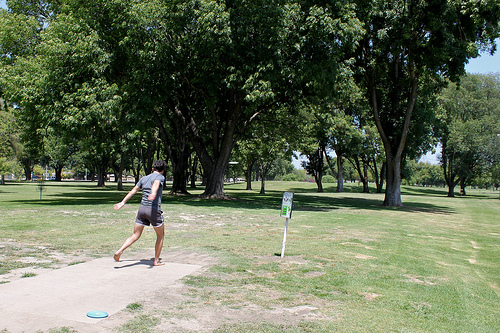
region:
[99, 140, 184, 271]
A man running in a field.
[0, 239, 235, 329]
a patch of dirt in a field.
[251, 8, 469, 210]
A tall green leafy tree.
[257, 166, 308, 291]
a sign near a patch of dirt.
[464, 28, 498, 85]
a section of a blue sky.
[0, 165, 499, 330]
a park with lots of green grass.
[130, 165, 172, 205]
a man wearing a gray t shirt.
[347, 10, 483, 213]
a tree with lots of green leaves.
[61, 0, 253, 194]
a tall leafy green tree.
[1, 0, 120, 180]
a tree with lots of leaves.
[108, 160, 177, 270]
This is a person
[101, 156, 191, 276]
This is a woman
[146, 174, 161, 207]
Hand of a person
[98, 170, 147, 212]
Hand of a person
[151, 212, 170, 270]
Leg of a person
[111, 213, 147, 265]
Leg of a person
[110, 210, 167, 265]
Legs of a person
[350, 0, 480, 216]
This is a tree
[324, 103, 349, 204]
This is a tree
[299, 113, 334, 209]
This is a tree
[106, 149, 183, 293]
man playing in park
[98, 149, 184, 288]
young man playing in park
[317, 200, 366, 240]
short green and brown grass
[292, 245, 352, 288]
short green and brown grass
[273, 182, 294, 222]
green and white sign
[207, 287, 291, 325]
short green and brown grass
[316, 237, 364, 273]
short green and brown grass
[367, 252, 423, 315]
short green and brown grass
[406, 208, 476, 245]
short green and brown grass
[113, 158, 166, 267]
man practicing yoga in a park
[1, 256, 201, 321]
yoga mat on grass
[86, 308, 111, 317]
green disc resting on a yoga mat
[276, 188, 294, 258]
green sign with white post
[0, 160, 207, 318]
man standing on a yoga mat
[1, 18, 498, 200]
trees in a park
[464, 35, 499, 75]
blue sky showing between trees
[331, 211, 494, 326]
grass in a park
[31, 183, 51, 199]
small shrub in a park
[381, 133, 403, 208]
trunk of a large tree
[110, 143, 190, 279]
this is a person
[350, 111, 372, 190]
this is a tree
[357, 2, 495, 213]
this is a tree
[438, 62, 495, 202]
this is a tree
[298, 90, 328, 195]
this is a tree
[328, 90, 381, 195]
this is a tree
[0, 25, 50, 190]
this is a tree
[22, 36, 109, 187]
this is a tree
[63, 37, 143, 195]
this is a tree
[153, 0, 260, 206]
this is a tree